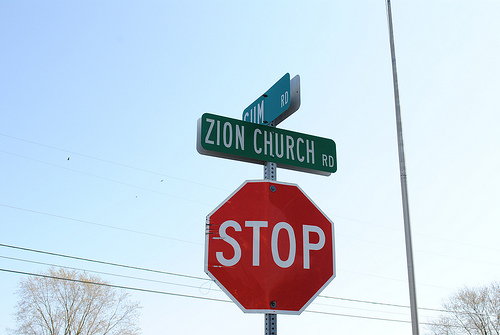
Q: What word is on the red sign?
A: Stop.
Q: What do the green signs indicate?
A: Street names.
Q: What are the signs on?
A: Pole.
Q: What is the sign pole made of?
A: Metal.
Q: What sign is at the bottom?
A: Stop sign.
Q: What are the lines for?
A: Power.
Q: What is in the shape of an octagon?
A: The stop sign.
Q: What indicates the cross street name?
A: The green and white street sign.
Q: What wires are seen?
A: Power lines.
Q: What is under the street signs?
A: A stop sign.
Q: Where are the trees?
A: Near the intersection.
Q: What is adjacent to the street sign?
A: A tall pole.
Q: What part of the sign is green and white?
A: The street signs.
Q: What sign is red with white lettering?
A: The stop sign.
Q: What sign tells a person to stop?
A: The red and white one.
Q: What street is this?
A: Zion Church Rd.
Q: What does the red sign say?
A: Stop.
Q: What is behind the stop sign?
A: Utility lines.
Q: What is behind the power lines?
A: Trees.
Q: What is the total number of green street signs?
A: Two.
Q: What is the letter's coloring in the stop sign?
A: White.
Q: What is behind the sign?
A: Trees.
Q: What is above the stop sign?
A: Street.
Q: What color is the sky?
A: Blue.